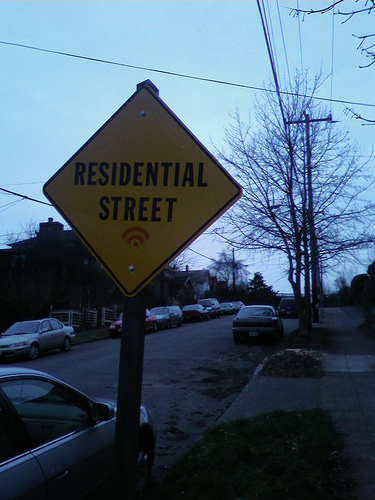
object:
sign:
[41, 79, 242, 299]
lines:
[0, 41, 374, 108]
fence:
[100, 306, 116, 326]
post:
[284, 110, 332, 324]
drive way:
[107, 344, 199, 421]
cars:
[181, 304, 206, 323]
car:
[0, 315, 77, 361]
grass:
[238, 440, 292, 474]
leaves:
[306, 353, 324, 371]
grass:
[260, 354, 307, 375]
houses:
[6, 217, 64, 292]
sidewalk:
[322, 305, 374, 499]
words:
[97, 195, 177, 224]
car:
[108, 309, 155, 337]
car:
[229, 305, 283, 340]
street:
[167, 314, 227, 349]